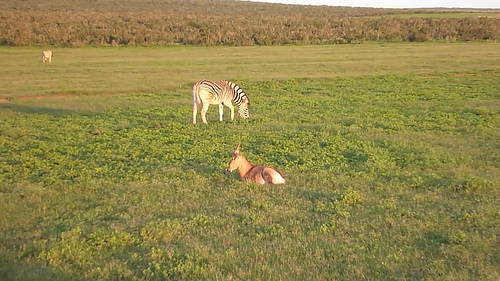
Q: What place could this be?
A: It is a field.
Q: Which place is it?
A: It is a field.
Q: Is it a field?
A: Yes, it is a field.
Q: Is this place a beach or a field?
A: It is a field.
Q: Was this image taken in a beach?
A: No, the picture was taken in a field.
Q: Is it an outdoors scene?
A: Yes, it is outdoors.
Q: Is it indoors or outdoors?
A: It is outdoors.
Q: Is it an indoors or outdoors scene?
A: It is outdoors.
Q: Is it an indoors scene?
A: No, it is outdoors.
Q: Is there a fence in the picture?
A: No, there are no fences.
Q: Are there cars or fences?
A: No, there are no fences or cars.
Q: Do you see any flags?
A: No, there are no flags.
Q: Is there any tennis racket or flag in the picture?
A: No, there are no flags or rackets.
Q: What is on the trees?
A: The leaves are on the trees.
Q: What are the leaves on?
A: The leaves are on the trees.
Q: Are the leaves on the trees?
A: Yes, the leaves are on the trees.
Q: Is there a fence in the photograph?
A: No, there are no fences.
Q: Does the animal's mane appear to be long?
A: Yes, the mane is long.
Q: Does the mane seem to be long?
A: Yes, the mane is long.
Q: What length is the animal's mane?
A: The mane is long.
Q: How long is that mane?
A: The mane is long.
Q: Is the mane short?
A: No, the mane is long.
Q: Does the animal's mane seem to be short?
A: No, the mane is long.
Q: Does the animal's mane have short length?
A: No, the mane is long.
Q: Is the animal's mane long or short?
A: The mane is long.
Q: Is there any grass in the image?
A: Yes, there is grass.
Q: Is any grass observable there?
A: Yes, there is grass.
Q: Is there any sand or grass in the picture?
A: Yes, there is grass.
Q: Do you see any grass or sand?
A: Yes, there is grass.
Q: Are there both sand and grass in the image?
A: No, there is grass but no sand.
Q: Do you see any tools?
A: No, there are no tools.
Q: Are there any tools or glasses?
A: No, there are no tools or glasses.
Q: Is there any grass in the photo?
A: Yes, there is grass.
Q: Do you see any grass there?
A: Yes, there is grass.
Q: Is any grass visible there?
A: Yes, there is grass.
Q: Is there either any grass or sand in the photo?
A: Yes, there is grass.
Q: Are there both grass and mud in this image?
A: No, there is grass but no mud.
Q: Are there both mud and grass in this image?
A: No, there is grass but no mud.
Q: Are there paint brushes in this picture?
A: No, there are no paint brushes.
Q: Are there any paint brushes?
A: No, there are no paint brushes.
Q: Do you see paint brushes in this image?
A: No, there are no paint brushes.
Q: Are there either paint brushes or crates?
A: No, there are no paint brushes or crates.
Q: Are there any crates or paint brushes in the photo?
A: No, there are no paint brushes or crates.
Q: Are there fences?
A: No, there are no fences.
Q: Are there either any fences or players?
A: No, there are no fences or players.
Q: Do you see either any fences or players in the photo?
A: No, there are no fences or players.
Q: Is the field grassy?
A: Yes, the field is grassy.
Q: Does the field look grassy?
A: Yes, the field is grassy.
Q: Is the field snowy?
A: No, the field is grassy.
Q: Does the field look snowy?
A: No, the field is grassy.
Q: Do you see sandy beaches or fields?
A: No, there is a field but it is grassy.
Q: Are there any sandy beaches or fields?
A: No, there is a field but it is grassy.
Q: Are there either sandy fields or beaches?
A: No, there is a field but it is grassy.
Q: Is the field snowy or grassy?
A: The field is grassy.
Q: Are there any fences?
A: No, there are no fences.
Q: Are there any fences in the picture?
A: No, there are no fences.